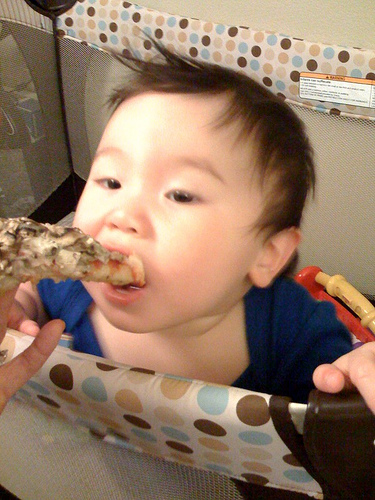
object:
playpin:
[0, 2, 373, 499]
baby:
[0, 3, 374, 498]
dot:
[305, 57, 317, 70]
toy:
[309, 264, 375, 341]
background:
[1, 2, 373, 291]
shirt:
[36, 273, 351, 404]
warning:
[296, 71, 375, 111]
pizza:
[0, 208, 150, 294]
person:
[2, 278, 67, 408]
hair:
[100, 21, 317, 248]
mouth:
[100, 248, 147, 302]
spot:
[337, 50, 349, 62]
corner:
[27, 0, 77, 17]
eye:
[165, 186, 205, 205]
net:
[59, 39, 374, 296]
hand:
[311, 342, 373, 418]